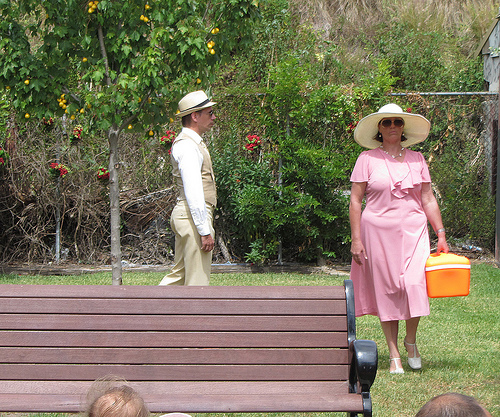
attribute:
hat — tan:
[171, 84, 218, 121]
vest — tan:
[167, 129, 220, 210]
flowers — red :
[46, 157, 73, 178]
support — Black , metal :
[343, 280, 383, 413]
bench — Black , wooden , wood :
[0, 278, 380, 415]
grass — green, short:
[3, 262, 498, 415]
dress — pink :
[349, 147, 434, 319]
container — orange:
[418, 235, 470, 298]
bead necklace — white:
[370, 131, 445, 173]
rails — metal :
[342, 277, 379, 414]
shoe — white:
[380, 361, 408, 376]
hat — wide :
[343, 102, 438, 147]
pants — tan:
[155, 200, 214, 287]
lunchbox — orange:
[424, 248, 471, 303]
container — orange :
[419, 245, 486, 306]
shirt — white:
[180, 151, 197, 188]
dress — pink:
[334, 144, 439, 324]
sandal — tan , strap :
[383, 332, 425, 379]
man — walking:
[163, 80, 228, 293]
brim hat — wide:
[353, 103, 431, 147]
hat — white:
[172, 87, 219, 119]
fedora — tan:
[173, 89, 219, 116]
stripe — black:
[181, 97, 211, 112]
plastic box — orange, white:
[426, 255, 471, 302]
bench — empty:
[5, 273, 405, 415]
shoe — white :
[399, 332, 427, 368]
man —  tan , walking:
[156, 89, 219, 289]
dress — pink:
[319, 133, 481, 336]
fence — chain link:
[435, 93, 493, 200]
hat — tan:
[352, 106, 428, 122]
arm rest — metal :
[342, 280, 378, 410]